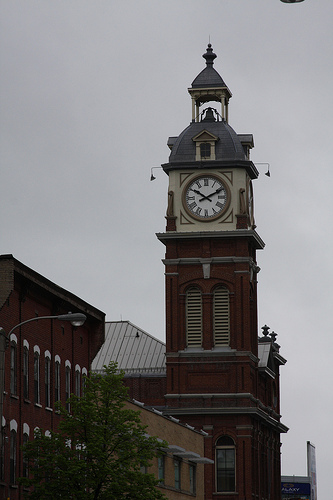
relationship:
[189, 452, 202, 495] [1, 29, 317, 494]
window of building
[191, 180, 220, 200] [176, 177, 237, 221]
black hands on clock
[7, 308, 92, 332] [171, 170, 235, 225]
light near clock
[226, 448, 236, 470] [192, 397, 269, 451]
window of building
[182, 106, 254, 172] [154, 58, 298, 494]
window of building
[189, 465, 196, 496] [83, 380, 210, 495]
window of building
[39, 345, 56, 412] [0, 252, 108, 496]
window of building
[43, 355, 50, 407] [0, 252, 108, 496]
window of building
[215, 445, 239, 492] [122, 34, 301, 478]
window of building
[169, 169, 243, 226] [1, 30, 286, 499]
clock on a building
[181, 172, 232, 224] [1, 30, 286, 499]
clock on a building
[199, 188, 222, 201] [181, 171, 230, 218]
black hands on a clock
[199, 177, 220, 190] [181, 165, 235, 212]
numbers on a clock